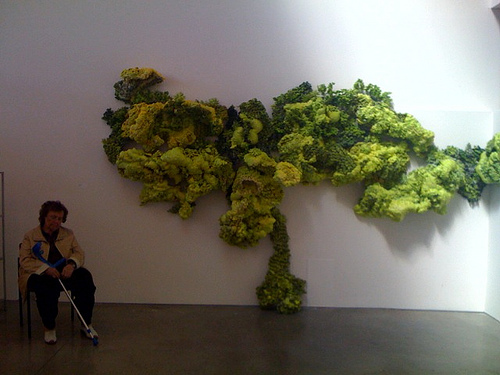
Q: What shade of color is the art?
A: Green.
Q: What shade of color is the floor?
A: Brown.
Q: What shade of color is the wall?
A: White.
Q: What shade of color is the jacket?
A: Brown.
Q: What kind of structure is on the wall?
A: Sculpted art.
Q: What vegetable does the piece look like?
A: Broccoli.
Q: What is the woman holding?
A: Walking cane.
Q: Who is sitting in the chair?
A: A woman.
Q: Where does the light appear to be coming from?
A: Overhead.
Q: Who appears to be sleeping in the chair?
A: An old woman.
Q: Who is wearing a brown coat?
A: The old woman.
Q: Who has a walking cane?
A: The old woman.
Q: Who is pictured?
A: A woman.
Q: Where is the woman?
A: In a chair.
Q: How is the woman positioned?
A: Sitting.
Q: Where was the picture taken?
A: A museum.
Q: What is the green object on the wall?
A: An art piece.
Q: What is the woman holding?
A: A cane.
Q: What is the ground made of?
A: Cement.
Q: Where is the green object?
A: On the wall.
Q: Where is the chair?
A: In the corner.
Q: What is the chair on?
A: The ground.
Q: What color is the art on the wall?
A: Green.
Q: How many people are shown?
A: 1.